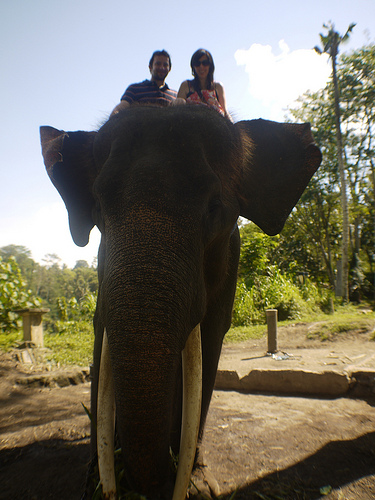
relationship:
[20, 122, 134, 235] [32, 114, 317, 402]
ear of elephant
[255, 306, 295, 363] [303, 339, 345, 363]
pole on top of ground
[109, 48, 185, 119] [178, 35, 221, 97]
man and woman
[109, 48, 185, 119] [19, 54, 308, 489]
man riding elephant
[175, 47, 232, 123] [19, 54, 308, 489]
person riding elephant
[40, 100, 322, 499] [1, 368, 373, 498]
elephant standing on concrete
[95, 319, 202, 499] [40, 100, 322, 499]
tusks on elephant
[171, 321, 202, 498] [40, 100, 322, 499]
tusk of elephant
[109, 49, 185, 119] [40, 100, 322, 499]
man riding atop elephant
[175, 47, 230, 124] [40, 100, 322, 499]
person riding atop elephant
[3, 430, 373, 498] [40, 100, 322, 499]
shadow of elephant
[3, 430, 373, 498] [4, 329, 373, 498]
shadow on ground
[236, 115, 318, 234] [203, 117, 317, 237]
ear of elephant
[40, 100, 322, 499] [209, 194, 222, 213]
elephant has eye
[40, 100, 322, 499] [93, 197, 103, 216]
elephant has eye